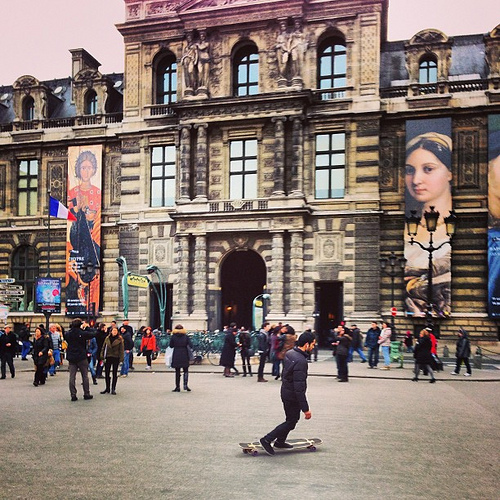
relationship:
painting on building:
[60, 138, 103, 321] [43, 46, 443, 314]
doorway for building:
[212, 245, 269, 336] [43, 46, 443, 314]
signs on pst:
[0, 262, 27, 310] [4, 305, 21, 326]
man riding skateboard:
[258, 330, 316, 457] [235, 438, 324, 456]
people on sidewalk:
[69, 312, 351, 390] [317, 364, 437, 385]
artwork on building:
[406, 121, 458, 303] [43, 46, 443, 314]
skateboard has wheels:
[235, 438, 324, 456] [240, 443, 262, 458]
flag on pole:
[47, 193, 72, 239] [47, 219, 51, 285]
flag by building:
[47, 193, 72, 239] [43, 46, 443, 314]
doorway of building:
[189, 227, 318, 359] [43, 46, 443, 314]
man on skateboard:
[214, 318, 356, 465] [235, 438, 324, 456]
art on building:
[27, 259, 68, 310] [43, 46, 443, 314]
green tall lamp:
[122, 256, 135, 313] [110, 243, 164, 357]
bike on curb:
[199, 325, 225, 366] [202, 367, 229, 371]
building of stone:
[43, 46, 443, 314] [345, 233, 372, 320]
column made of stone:
[271, 230, 291, 318] [345, 233, 372, 320]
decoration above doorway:
[312, 230, 361, 276] [311, 277, 347, 353]